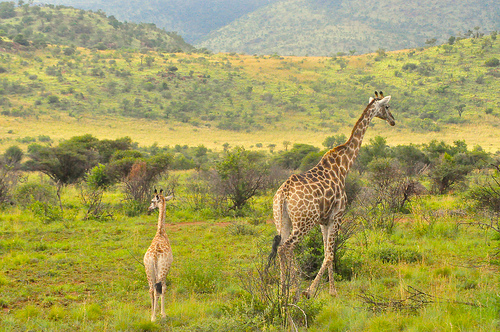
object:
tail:
[151, 254, 163, 294]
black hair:
[267, 235, 281, 271]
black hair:
[153, 282, 163, 294]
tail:
[263, 184, 288, 274]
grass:
[0, 190, 499, 332]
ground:
[0, 295, 500, 332]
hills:
[2, 0, 497, 131]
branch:
[342, 284, 488, 315]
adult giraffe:
[271, 89, 397, 299]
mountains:
[0, 0, 500, 121]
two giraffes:
[145, 90, 395, 322]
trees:
[0, 0, 500, 217]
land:
[7, 124, 498, 329]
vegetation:
[2, 135, 498, 330]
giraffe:
[143, 185, 172, 321]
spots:
[324, 188, 334, 199]